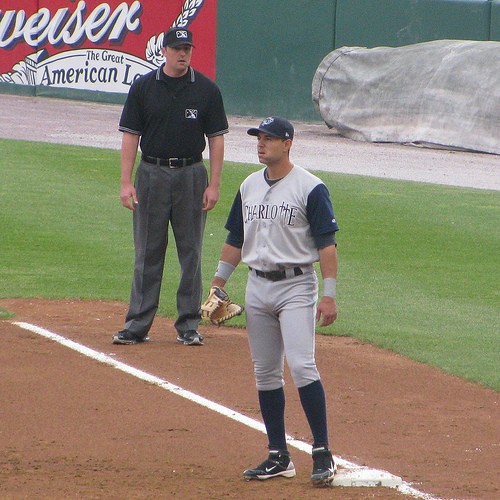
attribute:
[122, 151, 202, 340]
khakis — gray 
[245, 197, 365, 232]
lettering — black 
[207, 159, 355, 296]
jersey — grey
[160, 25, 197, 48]
cap — black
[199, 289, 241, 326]
mitt — leather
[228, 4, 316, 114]
wall — green 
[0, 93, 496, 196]
tan dirt — tan 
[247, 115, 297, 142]
hat — dark blue, white 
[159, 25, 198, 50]
hat — dark blue, white 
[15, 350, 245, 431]
white stripe — white 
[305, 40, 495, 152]
tarp — rolled up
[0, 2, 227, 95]
sign — red 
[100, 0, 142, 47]
white letter — white 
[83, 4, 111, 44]
white letter — white 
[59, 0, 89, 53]
white letter — white 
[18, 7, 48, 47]
white letter — white 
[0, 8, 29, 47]
white letter — white 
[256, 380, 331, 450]
socks — dark blue, knee high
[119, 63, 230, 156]
shirt — black 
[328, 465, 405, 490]
base — white 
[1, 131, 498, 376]
grass — green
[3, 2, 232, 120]
advertisement — white , red 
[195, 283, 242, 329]
glove — light brown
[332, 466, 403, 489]
plate — white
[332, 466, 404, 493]
base — white 